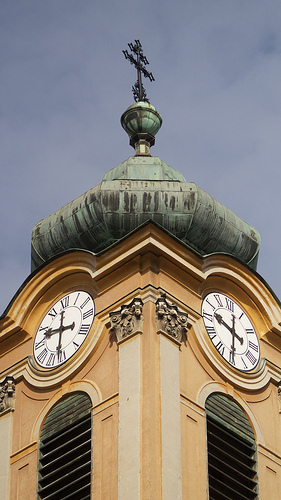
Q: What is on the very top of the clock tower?
A: A weather vane.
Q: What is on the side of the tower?
A: Two clocks.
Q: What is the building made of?
A: Stone.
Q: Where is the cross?
A: On top of the clock tower.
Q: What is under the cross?
A: A copper structure.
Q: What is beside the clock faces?
A: Carvings in the building.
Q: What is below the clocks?
A: Shuttered windows.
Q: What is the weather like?
A: Clear with a few thin clouds.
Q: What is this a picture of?
A: A historical clock tower.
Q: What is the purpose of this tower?
A: To tell time.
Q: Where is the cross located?
A: On the top.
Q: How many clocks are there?
A: Two.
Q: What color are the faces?
A: White.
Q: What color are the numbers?
A: Black.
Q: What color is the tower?
A: Tan.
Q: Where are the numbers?
A: On clock.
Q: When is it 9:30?
A: Now.